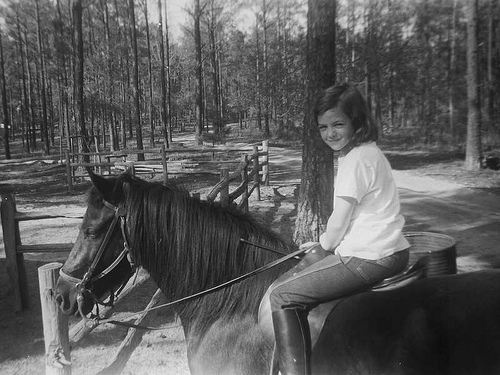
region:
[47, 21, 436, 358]
girl riding a pony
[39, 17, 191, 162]
wooded area for riding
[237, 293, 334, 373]
boots for horse riding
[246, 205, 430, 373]
English style saddle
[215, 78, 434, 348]
Girl riding English style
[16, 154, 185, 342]
pony wearing halter and bridle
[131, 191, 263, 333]
mane of a pony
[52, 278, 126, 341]
horse biting down on bit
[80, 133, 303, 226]
wooden fence posts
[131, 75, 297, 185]
road winding through trees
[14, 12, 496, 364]
Picture is taken outside.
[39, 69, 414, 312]
Picture is taken during the day.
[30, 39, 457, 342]
The whole picture is black and white.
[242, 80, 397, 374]
A girl is on a horse.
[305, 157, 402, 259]
The girl is wearing a white shirt.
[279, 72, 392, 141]
The girl has medium length hair.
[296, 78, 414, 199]
The girl is smiling.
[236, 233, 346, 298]
The girl is holding the reins.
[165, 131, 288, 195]
A wood fence is next to the horse.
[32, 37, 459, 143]
Tall trees in the background.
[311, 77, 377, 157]
the head of a girl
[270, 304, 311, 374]
a black boot on the girl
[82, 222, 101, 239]
the eye of a horse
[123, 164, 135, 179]
the ear of a horse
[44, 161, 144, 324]
the head of a horse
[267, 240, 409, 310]
a pair of jeans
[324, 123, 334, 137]
the nose of the girl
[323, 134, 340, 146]
the mouth of the girl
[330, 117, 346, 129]
the eye of the girl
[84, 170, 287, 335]
the mane of the horse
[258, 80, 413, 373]
girl in white shirt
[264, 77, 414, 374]
girl sitting on horse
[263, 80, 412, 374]
girl with short hair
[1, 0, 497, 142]
trees in the background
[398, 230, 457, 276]
top of large metal can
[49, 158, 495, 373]
dark colored horse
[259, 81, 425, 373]
girl holding reins of horse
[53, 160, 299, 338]
horse with smooth mane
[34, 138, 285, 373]
wooden fence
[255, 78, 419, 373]
girl wearing jeans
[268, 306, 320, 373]
top of boot on left leg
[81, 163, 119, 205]
left ear of horse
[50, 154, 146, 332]
the entire horses head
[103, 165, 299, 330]
top to bottom of horses mane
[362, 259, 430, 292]
back end of saddle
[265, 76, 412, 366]
the rider on horse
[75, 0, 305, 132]
trees in the forrest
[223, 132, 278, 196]
corner of wooden fence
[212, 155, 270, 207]
the wooden fence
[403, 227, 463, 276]
metal barrel behind horse